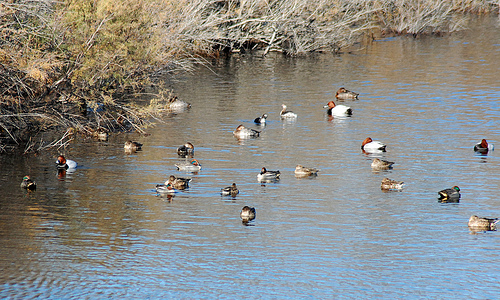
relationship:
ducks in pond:
[14, 81, 497, 241] [8, 32, 500, 300]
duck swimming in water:
[14, 81, 497, 241] [8, 32, 500, 300]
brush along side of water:
[0, 2, 450, 105] [3, 81, 500, 299]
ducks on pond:
[14, 81, 497, 241] [8, 32, 500, 300]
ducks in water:
[14, 81, 497, 241] [3, 81, 500, 299]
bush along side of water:
[0, 2, 450, 105] [3, 81, 500, 299]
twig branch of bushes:
[14, 6, 312, 52] [4, 0, 457, 61]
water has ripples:
[3, 81, 500, 299] [33, 230, 425, 286]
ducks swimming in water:
[14, 81, 497, 241] [3, 81, 500, 299]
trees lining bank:
[4, 0, 457, 61] [5, 5, 498, 74]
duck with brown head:
[379, 174, 408, 194] [380, 172, 392, 184]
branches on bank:
[164, 5, 474, 47] [5, 5, 498, 74]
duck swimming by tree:
[151, 89, 194, 118] [0, 0, 164, 123]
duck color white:
[358, 134, 390, 158] [366, 141, 385, 153]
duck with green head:
[434, 182, 466, 206] [451, 184, 463, 193]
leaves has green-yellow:
[0, 0, 164, 123] [43, 2, 174, 95]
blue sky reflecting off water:
[33, 230, 425, 286] [3, 81, 500, 299]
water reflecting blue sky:
[3, 81, 500, 299] [33, 230, 425, 286]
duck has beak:
[322, 100, 356, 121] [322, 103, 331, 111]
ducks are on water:
[14, 81, 497, 241] [3, 81, 500, 299]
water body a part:
[3, 81, 500, 299] [8, 32, 500, 300]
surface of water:
[8, 32, 500, 300] [3, 81, 500, 299]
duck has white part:
[322, 100, 356, 121] [331, 105, 348, 117]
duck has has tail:
[291, 162, 321, 181] [312, 167, 323, 177]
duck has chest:
[291, 162, 321, 181] [294, 170, 304, 177]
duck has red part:
[472, 134, 499, 160] [478, 137, 490, 150]